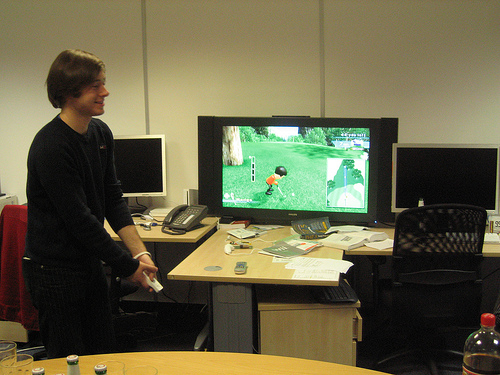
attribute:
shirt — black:
[27, 121, 132, 261]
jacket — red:
[1, 203, 51, 335]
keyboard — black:
[316, 282, 357, 305]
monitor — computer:
[112, 131, 213, 228]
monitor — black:
[82, 122, 192, 229]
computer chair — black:
[372, 203, 499, 335]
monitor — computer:
[392, 136, 499, 226]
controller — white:
[136, 259, 163, 292]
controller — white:
[126, 264, 163, 293]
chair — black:
[382, 201, 490, 368]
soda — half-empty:
[465, 354, 497, 372]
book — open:
[316, 225, 363, 252]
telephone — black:
[159, 198, 210, 235]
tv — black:
[159, 83, 425, 256]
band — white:
[127, 247, 154, 258]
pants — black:
[21, 254, 127, 356]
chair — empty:
[365, 204, 494, 374]